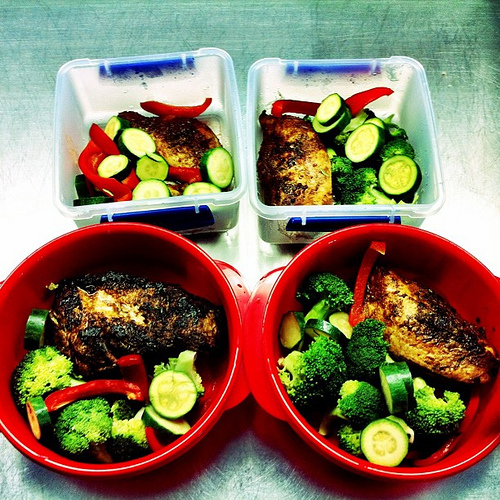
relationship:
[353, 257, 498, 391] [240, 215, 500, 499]
meat in bowl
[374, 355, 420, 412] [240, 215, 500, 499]
cucumber in bowl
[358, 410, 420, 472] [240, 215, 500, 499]
cucumber in bowl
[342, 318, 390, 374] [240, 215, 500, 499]
broccoli in bowl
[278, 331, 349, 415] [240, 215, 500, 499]
broccoli in bowl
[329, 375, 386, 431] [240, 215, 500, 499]
broccoli in bowl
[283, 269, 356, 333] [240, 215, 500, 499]
broccoli in bowl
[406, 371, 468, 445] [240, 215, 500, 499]
broccoli in bowl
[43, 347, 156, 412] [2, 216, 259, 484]
peppers in bowl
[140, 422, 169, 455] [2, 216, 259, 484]
peppers in bowl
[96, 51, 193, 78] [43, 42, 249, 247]
handle on container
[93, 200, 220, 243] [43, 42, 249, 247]
handle on container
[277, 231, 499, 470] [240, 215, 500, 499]
dinner in bowl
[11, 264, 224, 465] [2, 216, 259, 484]
dinner in bowl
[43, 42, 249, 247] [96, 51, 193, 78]
container with handle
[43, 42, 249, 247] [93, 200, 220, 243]
container with handle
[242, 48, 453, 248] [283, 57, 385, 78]
container with handle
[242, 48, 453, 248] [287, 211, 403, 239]
container with handle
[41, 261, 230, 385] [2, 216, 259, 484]
meat in bowl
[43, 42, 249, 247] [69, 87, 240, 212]
container with meal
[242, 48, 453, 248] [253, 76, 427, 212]
container with meal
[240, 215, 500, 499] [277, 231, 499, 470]
bowl with dinner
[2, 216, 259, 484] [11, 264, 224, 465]
bowl with dinner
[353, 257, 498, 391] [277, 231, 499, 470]
meat with dinner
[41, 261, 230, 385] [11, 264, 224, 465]
meat with dinner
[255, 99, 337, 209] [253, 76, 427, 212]
meat with meal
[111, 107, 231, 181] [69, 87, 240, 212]
meat with meal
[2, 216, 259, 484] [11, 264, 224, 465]
bowl contains dinner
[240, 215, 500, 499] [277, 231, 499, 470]
bowl contains dinner